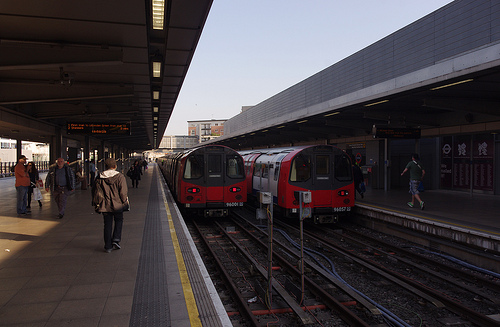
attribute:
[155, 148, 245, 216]
train — red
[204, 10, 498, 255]
station — of railway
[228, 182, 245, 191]
light — on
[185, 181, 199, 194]
light — on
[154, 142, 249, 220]
train — two passenger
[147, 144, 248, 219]
train — red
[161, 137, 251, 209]
train — same color